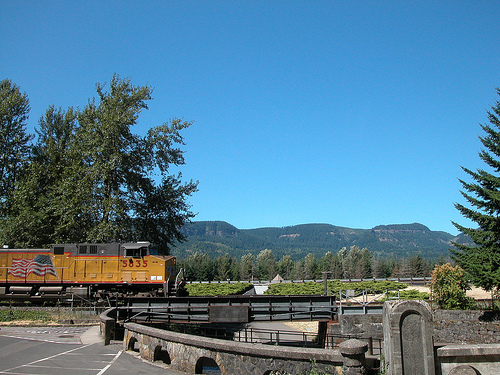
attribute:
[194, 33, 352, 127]
sky — clear, blue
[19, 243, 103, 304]
flag — American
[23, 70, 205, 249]
tree — tall, leaf filled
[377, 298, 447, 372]
pillar — tall, cement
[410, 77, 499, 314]
tree — tall , pine 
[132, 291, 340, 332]
bridge — small, train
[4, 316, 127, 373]
parking lot — paved